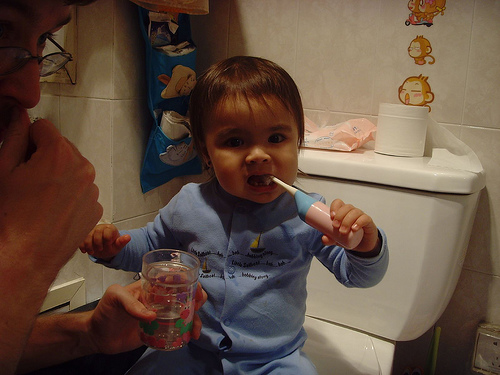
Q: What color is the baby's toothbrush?
A: Pink, blue, and white.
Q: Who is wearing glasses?
A: The man.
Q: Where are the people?
A: In the bathroom.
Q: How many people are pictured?
A: Two.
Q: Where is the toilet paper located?
A: On the toilet tank.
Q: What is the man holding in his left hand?
A: A glass.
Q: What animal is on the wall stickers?
A: Monkey.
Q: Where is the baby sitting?
A: On the toilet.